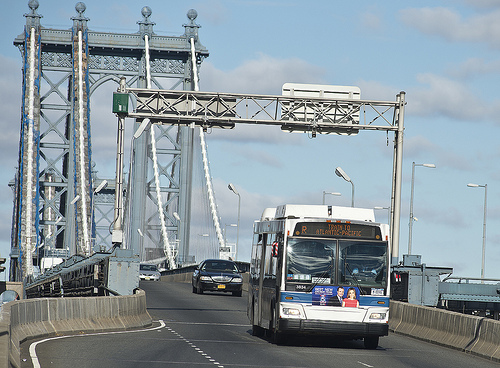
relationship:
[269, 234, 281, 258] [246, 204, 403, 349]
mirror on bus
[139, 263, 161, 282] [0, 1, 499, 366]
cars coming across bridge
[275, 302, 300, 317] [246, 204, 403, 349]
headlight on bus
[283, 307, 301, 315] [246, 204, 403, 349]
headlight on bus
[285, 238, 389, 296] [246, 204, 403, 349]
front on bus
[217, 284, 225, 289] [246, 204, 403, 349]
license plate on bus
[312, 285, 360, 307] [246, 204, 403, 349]
bus advertising on bus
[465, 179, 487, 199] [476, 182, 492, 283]
light on pole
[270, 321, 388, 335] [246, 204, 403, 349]
black bumper on bus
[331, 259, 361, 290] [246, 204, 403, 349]
wiper on bus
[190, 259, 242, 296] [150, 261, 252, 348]
car on street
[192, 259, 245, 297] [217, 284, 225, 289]
car with license plate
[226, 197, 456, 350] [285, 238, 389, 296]
bus has front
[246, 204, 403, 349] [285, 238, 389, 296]
bus has front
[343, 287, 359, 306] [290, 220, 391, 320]
woman on front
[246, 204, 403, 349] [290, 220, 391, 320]
bus has front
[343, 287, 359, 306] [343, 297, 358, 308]
woman in top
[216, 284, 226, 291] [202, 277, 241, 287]
license plate on front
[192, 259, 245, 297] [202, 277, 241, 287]
car has front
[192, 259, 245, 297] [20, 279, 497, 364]
car driving on road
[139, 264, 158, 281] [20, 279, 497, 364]
cars driving on road